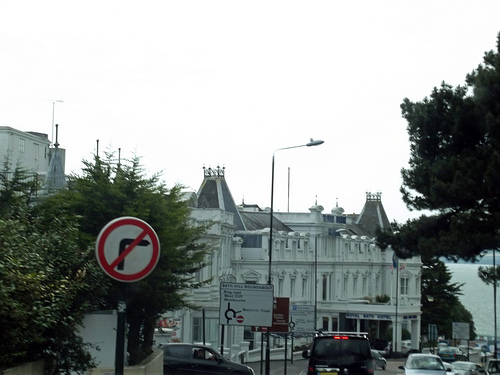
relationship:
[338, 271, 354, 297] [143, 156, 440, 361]
window on building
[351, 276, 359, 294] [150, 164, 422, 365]
window on building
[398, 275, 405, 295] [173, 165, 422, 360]
window on building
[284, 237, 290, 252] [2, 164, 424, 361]
window on building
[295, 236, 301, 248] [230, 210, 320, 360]
window on building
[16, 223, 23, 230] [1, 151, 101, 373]
leaf on plant